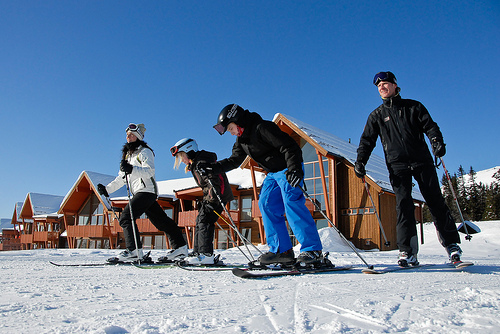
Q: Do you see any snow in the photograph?
A: Yes, there is snow.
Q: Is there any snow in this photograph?
A: Yes, there is snow.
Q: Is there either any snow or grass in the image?
A: Yes, there is snow.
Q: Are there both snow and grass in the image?
A: No, there is snow but no grass.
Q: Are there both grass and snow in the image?
A: No, there is snow but no grass.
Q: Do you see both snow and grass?
A: No, there is snow but no grass.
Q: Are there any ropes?
A: No, there are no ropes.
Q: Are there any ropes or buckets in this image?
A: No, there are no ropes or buckets.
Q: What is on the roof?
A: The snow is on the roof.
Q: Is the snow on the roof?
A: Yes, the snow is on the roof.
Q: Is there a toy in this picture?
A: No, there are no toys.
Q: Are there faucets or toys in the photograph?
A: No, there are no toys or faucets.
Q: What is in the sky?
A: The clouds are in the sky.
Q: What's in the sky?
A: The clouds are in the sky.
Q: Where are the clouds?
A: The clouds are in the sky.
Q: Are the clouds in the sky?
A: Yes, the clouds are in the sky.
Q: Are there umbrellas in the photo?
A: No, there are no umbrellas.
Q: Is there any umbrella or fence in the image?
A: No, there are no umbrellas or fences.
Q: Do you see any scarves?
A: Yes, there is a scarf.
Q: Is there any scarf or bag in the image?
A: Yes, there is a scarf.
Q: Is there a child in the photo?
A: Yes, there are children.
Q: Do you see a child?
A: Yes, there are children.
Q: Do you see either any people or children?
A: Yes, there are children.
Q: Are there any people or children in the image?
A: Yes, there are children.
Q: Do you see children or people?
A: Yes, there are children.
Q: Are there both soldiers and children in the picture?
A: No, there are children but no soldiers.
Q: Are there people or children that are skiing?
A: Yes, the children are skiing.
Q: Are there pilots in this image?
A: No, there are no pilots.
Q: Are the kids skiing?
A: Yes, the kids are skiing.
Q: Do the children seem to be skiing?
A: Yes, the children are skiing.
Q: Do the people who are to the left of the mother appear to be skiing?
A: Yes, the children are skiing.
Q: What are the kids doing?
A: The kids are skiing.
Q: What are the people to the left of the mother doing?
A: The kids are skiing.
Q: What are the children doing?
A: The kids are skiing.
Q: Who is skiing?
A: The children are skiing.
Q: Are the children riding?
A: No, the children are skiing.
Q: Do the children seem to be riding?
A: No, the children are skiing.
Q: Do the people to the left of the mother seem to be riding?
A: No, the children are skiing.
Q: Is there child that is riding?
A: No, there are children but they are skiing.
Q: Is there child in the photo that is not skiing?
A: No, there are children but they are skiing.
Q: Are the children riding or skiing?
A: The children are skiing.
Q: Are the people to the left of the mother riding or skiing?
A: The children are skiing.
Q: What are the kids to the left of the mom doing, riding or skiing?
A: The children are skiing.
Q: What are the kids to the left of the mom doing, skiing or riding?
A: The children are skiing.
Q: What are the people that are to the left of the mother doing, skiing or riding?
A: The children are skiing.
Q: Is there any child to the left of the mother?
A: Yes, there are children to the left of the mother.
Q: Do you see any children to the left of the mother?
A: Yes, there are children to the left of the mother.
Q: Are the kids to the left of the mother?
A: Yes, the kids are to the left of the mother.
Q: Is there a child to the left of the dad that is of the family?
A: Yes, there are children to the left of the father.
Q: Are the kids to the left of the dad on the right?
A: Yes, the kids are to the left of the dad.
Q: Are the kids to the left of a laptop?
A: No, the kids are to the left of the dad.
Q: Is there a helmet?
A: Yes, there is a helmet.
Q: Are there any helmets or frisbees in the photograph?
A: Yes, there is a helmet.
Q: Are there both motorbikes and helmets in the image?
A: No, there is a helmet but no motorcycles.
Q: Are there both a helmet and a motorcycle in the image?
A: No, there is a helmet but no motorcycles.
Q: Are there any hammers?
A: No, there are no hammers.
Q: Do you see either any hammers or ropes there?
A: No, there are no hammers or ropes.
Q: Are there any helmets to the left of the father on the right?
A: Yes, there is a helmet to the left of the father.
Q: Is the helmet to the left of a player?
A: No, the helmet is to the left of a father.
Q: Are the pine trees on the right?
A: Yes, the pine trees are on the right of the image.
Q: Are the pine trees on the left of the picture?
A: No, the pine trees are on the right of the image.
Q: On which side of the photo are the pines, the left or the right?
A: The pines are on the right of the image.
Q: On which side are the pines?
A: The pines are on the right of the image.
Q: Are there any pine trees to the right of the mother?
A: Yes, there are pine trees to the right of the mother.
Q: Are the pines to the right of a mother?
A: Yes, the pines are to the right of a mother.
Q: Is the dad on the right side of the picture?
A: Yes, the dad is on the right of the image.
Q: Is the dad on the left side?
A: No, the dad is on the right of the image.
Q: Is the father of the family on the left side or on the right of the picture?
A: The father is on the right of the image.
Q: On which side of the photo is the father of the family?
A: The dad is on the right of the image.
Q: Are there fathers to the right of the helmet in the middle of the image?
A: Yes, there is a father to the right of the helmet.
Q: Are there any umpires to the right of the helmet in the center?
A: No, there is a father to the right of the helmet.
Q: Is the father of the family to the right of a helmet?
A: Yes, the father is to the right of a helmet.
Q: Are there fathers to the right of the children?
A: Yes, there is a father to the right of the children.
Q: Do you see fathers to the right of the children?
A: Yes, there is a father to the right of the children.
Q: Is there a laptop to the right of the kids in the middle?
A: No, there is a father to the right of the kids.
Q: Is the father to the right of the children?
A: Yes, the father is to the right of the children.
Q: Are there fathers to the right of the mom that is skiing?
A: Yes, there is a father to the right of the mother.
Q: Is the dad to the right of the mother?
A: Yes, the dad is to the right of the mother.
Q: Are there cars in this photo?
A: No, there are no cars.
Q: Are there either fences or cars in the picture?
A: No, there are no cars or fences.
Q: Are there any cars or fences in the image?
A: No, there are no cars or fences.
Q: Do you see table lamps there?
A: No, there are no table lamps.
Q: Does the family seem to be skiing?
A: Yes, the family is skiing.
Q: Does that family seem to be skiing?
A: Yes, the family is skiing.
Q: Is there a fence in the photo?
A: No, there are no fences.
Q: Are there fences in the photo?
A: No, there are no fences.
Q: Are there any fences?
A: No, there are no fences.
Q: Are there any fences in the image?
A: No, there are no fences.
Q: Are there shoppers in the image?
A: No, there are no shoppers.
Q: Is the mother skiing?
A: Yes, the mother is skiing.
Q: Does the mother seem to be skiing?
A: Yes, the mother is skiing.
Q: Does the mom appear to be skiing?
A: Yes, the mom is skiing.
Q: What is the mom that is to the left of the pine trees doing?
A: The mother is skiing.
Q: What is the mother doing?
A: The mother is skiing.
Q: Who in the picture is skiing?
A: The mother is skiing.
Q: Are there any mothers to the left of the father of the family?
A: Yes, there is a mother to the left of the father.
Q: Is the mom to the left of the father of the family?
A: Yes, the mom is to the left of the father.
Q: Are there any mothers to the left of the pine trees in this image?
A: Yes, there is a mother to the left of the pine trees.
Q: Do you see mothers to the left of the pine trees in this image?
A: Yes, there is a mother to the left of the pine trees.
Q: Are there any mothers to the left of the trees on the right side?
A: Yes, there is a mother to the left of the pine trees.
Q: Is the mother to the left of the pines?
A: Yes, the mother is to the left of the pines.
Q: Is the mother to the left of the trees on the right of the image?
A: Yes, the mother is to the left of the pines.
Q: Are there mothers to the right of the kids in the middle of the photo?
A: Yes, there is a mother to the right of the children.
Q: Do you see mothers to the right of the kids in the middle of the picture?
A: Yes, there is a mother to the right of the children.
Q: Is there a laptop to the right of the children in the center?
A: No, there is a mother to the right of the kids.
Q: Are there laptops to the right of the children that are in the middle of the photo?
A: No, there is a mother to the right of the kids.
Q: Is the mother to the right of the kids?
A: Yes, the mother is to the right of the kids.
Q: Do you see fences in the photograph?
A: No, there are no fences.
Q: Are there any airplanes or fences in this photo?
A: No, there are no fences or airplanes.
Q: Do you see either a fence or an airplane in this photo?
A: No, there are no fences or airplanes.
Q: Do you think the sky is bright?
A: Yes, the sky is bright.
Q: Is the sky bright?
A: Yes, the sky is bright.